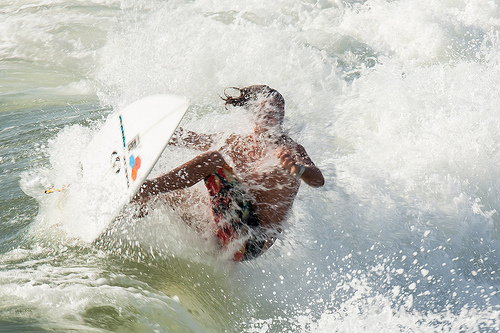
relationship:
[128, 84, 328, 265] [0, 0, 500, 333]
person in ocean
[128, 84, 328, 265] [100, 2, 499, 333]
person riding wave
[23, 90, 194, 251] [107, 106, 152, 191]
surfboard has stickers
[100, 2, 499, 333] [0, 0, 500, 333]
wave in ocean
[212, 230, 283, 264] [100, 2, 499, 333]
butt touching wave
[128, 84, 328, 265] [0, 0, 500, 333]
man in ocean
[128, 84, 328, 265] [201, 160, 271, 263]
person wearing shorts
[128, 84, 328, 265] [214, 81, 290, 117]
person has hair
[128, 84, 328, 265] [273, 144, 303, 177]
person has hand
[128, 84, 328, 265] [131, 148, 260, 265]
person has leg